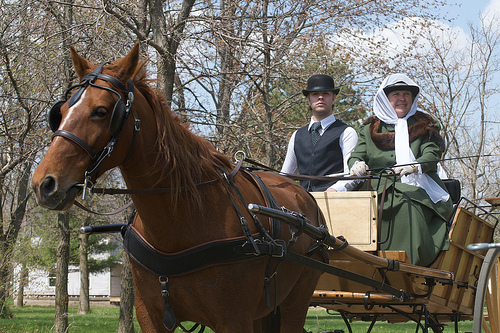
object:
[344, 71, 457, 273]
woman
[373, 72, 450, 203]
scarf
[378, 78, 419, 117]
head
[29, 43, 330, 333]
horse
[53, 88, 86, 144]
marker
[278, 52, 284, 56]
leaves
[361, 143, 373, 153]
green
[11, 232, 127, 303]
white house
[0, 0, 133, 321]
tree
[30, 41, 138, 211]
head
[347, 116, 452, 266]
jacket